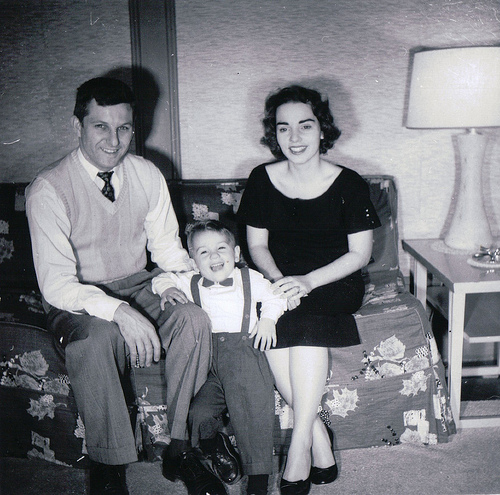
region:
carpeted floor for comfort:
[341, 451, 499, 493]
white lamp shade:
[401, 44, 498, 125]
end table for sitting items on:
[404, 236, 499, 426]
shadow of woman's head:
[316, 78, 356, 140]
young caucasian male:
[148, 219, 287, 494]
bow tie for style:
[200, 275, 235, 287]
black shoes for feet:
[280, 425, 337, 493]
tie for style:
[92, 173, 117, 207]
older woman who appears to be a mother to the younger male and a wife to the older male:
[233, 84, 381, 494]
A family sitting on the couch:
[7, 63, 413, 493]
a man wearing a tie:
[23, 69, 218, 481]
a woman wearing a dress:
[232, 91, 387, 480]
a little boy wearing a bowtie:
[151, 213, 290, 468]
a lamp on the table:
[368, 19, 493, 250]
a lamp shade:
[394, 33, 496, 153]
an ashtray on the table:
[472, 235, 497, 285]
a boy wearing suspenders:
[146, 220, 296, 445]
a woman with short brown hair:
[218, 64, 381, 439]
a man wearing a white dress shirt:
[16, 63, 219, 444]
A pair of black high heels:
[276, 419, 340, 493]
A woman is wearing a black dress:
[233, 81, 383, 353]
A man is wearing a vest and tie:
[19, 69, 191, 284]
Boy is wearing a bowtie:
[181, 216, 250, 296]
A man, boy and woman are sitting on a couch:
[2, 65, 461, 492]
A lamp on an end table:
[394, 54, 498, 289]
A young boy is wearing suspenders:
[148, 216, 293, 494]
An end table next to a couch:
[399, 227, 499, 426]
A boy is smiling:
[179, 218, 250, 289]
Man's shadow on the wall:
[101, 60, 187, 180]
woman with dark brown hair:
[242, 72, 383, 492]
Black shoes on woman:
[279, 416, 346, 493]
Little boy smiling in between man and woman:
[142, 220, 310, 490]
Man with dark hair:
[20, 71, 224, 492]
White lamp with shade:
[395, 33, 499, 267]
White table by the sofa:
[402, 226, 499, 431]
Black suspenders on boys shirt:
[184, 267, 257, 346]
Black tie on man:
[91, 171, 121, 205]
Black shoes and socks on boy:
[200, 427, 275, 494]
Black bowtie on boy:
[197, 270, 236, 300]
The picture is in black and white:
[4, 5, 491, 491]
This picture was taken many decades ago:
[28, 43, 483, 479]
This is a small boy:
[151, 204, 296, 489]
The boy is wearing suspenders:
[180, 265, 270, 335]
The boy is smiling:
[178, 205, 253, 279]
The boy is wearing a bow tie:
[194, 265, 245, 295]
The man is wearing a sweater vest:
[39, 155, 181, 285]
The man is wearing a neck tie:
[97, 168, 121, 198]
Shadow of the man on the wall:
[122, 52, 186, 167]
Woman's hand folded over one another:
[273, 268, 309, 315]